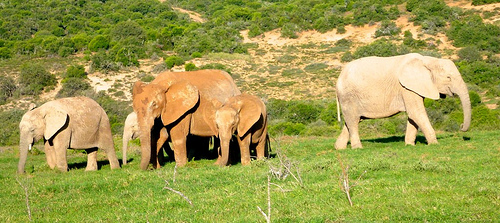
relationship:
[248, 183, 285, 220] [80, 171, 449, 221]
stick jutting ground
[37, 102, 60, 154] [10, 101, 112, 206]
ear of an elephant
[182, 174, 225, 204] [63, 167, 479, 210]
green grass on ground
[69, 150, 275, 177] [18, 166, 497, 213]
shadows on ground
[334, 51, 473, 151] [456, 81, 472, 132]
elephant has trunk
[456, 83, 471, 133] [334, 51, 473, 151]
trunk belonging to elephant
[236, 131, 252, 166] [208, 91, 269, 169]
leg belonging to elephant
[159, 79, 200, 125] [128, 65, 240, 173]
ear belonging to elephant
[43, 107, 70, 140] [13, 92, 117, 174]
ear belonging to elephant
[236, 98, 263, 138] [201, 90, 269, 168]
ear belonging to elephant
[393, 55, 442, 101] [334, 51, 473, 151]
ear belonging to elephant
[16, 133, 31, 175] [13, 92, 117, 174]
trunk belonging to elephant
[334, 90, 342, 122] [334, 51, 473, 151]
tail belonging to elephant